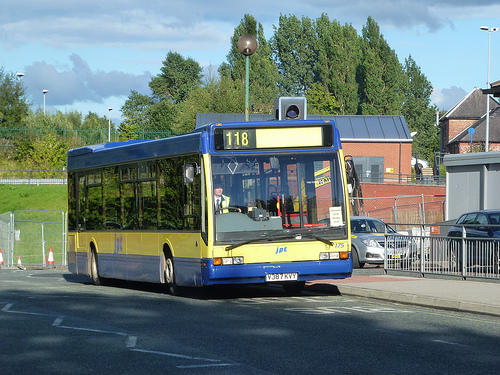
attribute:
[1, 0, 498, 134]
sky — partly cloudy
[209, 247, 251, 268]
headlights — off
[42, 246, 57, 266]
traffic cone — orange, white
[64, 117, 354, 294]
bus — yellow, blue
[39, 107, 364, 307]
bus — blue and yellow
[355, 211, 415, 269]
car — parked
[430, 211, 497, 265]
car — parked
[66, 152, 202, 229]
window — reflective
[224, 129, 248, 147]
numbers — yellow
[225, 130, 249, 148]
118 — number, bus route number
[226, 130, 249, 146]
118 — bus driver route